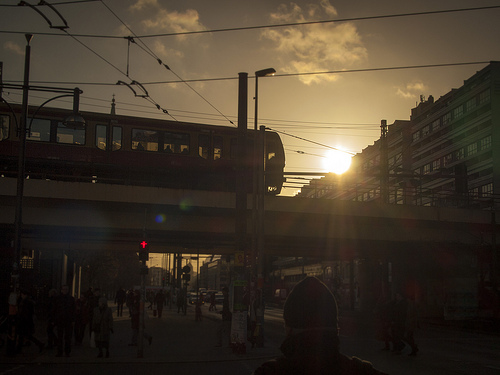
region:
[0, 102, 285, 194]
A metro train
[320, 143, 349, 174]
Setting sun in the evening sky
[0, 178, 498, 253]
The bridge of the monorail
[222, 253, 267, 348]
Pillar of the bridge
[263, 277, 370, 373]
Back of a person walking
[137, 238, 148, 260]
Signal on the road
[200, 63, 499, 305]
Buildings by the roadside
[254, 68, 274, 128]
A light and its post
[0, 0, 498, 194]
Sky full of several overhead electrical cables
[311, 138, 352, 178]
a glowing, setting sun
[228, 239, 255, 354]
a pole covered in posters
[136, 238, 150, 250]
a glowing red light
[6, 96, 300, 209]
a train on a bridge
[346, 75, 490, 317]
a tall building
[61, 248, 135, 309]
a tree on the sidewalk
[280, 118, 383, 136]
a few power lines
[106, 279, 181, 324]
a group of pedestrians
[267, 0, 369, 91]
some thin cloud formations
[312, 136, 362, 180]
The sun is setting.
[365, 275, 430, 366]
The people are crossing the street.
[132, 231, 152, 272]
The traffic light has a red cross.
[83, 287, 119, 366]
The lady is standing on the sidewalk.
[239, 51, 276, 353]
The light pole is standing next to the train.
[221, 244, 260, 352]
The pole has advertisments on it.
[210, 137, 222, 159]
glass window on train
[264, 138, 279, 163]
glass window on train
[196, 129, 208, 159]
glass window on train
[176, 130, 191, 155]
glass window on train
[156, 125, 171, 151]
glass window on train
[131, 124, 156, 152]
glass window on train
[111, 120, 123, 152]
glass window on train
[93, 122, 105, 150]
glass window on train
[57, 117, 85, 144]
glass window on train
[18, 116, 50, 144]
glass window on train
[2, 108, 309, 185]
train on the track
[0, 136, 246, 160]
windows of the train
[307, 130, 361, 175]
the sun is bright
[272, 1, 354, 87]
small clouds in sky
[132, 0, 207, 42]
small clouds in sky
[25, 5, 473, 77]
railing above the train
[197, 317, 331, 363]
the road is dark